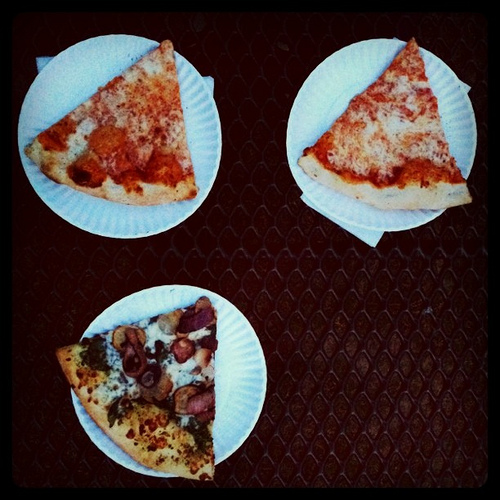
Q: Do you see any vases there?
A: No, there are no vases.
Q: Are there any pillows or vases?
A: No, there are no vases or pillows.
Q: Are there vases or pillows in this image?
A: No, there are no vases or pillows.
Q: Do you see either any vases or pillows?
A: No, there are no vases or pillows.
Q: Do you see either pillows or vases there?
A: No, there are no vases or pillows.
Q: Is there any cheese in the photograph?
A: Yes, there is cheese.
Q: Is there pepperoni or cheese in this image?
A: Yes, there is cheese.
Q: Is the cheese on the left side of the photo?
A: Yes, the cheese is on the left of the image.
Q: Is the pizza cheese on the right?
A: No, the cheese is on the left of the image.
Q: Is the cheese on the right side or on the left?
A: The cheese is on the left of the image.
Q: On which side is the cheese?
A: The cheese is on the left of the image.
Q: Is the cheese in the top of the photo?
A: Yes, the cheese is in the top of the image.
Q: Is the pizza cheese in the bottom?
A: No, the cheese is in the top of the image.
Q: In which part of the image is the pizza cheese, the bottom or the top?
A: The cheese is in the top of the image.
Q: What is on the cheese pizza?
A: The cheese is on the pizza.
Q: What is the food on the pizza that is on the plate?
A: The food is cheese.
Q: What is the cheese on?
A: The cheese is on the pizza.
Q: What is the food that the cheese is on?
A: The food is a pizza.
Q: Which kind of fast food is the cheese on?
A: The cheese is on the pizza.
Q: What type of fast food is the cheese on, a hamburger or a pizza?
A: The cheese is on a pizza.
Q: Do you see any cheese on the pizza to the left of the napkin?
A: Yes, there is cheese on the pizza.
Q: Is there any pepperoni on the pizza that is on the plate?
A: No, there is cheese on the pizza.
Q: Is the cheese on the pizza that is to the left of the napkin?
A: Yes, the cheese is on the pizza.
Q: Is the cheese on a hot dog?
A: No, the cheese is on the pizza.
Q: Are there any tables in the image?
A: Yes, there is a table.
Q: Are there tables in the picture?
A: Yes, there is a table.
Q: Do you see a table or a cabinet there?
A: Yes, there is a table.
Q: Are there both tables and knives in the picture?
A: No, there is a table but no knives.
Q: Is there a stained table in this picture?
A: Yes, there is a stained table.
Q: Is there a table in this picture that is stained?
A: Yes, there is a table that is stained.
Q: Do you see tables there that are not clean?
A: Yes, there is a stained table.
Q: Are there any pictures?
A: No, there are no pictures.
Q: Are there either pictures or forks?
A: No, there are no pictures or forks.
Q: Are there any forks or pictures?
A: No, there are no pictures or forks.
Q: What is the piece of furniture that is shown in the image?
A: The piece of furniture is a table.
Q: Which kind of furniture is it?
A: The piece of furniture is a table.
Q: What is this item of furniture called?
A: This is a table.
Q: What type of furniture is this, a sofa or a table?
A: This is a table.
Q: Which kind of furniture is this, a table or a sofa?
A: This is a table.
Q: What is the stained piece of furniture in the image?
A: The piece of furniture is a table.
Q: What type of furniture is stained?
A: The furniture is a table.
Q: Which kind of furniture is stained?
A: The furniture is a table.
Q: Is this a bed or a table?
A: This is a table.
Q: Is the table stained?
A: Yes, the table is stained.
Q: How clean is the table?
A: The table is stained.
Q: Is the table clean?
A: No, the table is stained.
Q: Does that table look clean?
A: No, the table is stained.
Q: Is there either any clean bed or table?
A: No, there is a table but it is stained.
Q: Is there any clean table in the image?
A: No, there is a table but it is stained.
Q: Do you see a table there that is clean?
A: No, there is a table but it is stained.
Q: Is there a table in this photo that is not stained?
A: No, there is a table but it is stained.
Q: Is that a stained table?
A: Yes, that is a stained table.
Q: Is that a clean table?
A: No, that is a stained table.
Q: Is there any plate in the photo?
A: Yes, there is a plate.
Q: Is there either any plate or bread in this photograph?
A: Yes, there is a plate.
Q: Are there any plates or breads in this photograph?
A: Yes, there is a plate.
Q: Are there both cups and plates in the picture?
A: No, there is a plate but no cups.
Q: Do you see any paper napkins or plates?
A: Yes, there is a paper plate.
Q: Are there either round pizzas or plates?
A: Yes, there is a round plate.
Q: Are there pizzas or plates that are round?
A: Yes, the plate is round.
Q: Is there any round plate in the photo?
A: Yes, there is a round plate.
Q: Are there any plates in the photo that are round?
A: Yes, there is a plate that is round.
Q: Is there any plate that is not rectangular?
A: Yes, there is a round plate.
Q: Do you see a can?
A: No, there are no cans.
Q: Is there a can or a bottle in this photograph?
A: No, there are no cans or bottles.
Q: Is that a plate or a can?
A: That is a plate.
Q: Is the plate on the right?
A: No, the plate is on the left of the image.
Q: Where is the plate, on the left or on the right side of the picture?
A: The plate is on the left of the image.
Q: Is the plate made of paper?
A: Yes, the plate is made of paper.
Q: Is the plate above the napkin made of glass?
A: No, the plate is made of paper.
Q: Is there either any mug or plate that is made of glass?
A: No, there is a plate but it is made of paper.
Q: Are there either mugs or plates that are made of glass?
A: No, there is a plate but it is made of paper.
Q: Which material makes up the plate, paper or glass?
A: The plate is made of paper.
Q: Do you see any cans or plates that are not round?
A: No, there is a plate but it is round.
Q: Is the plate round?
A: Yes, the plate is round.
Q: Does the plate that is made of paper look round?
A: Yes, the plate is round.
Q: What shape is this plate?
A: The plate is round.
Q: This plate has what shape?
A: The plate is round.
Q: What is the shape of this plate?
A: The plate is round.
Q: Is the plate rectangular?
A: No, the plate is round.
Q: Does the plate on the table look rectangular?
A: No, the plate is round.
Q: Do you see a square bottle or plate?
A: No, there is a plate but it is round.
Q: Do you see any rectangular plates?
A: No, there is a plate but it is round.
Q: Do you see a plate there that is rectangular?
A: No, there is a plate but it is round.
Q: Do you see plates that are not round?
A: No, there is a plate but it is round.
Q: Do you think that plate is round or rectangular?
A: The plate is round.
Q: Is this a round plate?
A: Yes, this is a round plate.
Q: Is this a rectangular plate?
A: No, this is a round plate.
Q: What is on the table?
A: The plate is on the table.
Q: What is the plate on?
A: The plate is on the table.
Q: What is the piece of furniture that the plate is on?
A: The piece of furniture is a table.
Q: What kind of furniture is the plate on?
A: The plate is on the table.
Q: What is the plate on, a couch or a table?
A: The plate is on a table.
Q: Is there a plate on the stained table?
A: Yes, there is a plate on the table.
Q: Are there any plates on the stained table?
A: Yes, there is a plate on the table.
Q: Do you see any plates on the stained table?
A: Yes, there is a plate on the table.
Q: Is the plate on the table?
A: Yes, the plate is on the table.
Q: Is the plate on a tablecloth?
A: No, the plate is on the table.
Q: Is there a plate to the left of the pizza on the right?
A: Yes, there is a plate to the left of the pizza.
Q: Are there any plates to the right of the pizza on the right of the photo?
A: No, the plate is to the left of the pizza.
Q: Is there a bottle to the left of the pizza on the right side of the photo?
A: No, there is a plate to the left of the pizza.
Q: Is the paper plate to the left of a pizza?
A: Yes, the plate is to the left of a pizza.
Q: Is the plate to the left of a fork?
A: No, the plate is to the left of a pizza.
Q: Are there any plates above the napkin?
A: Yes, there is a plate above the napkin.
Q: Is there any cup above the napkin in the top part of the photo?
A: No, there is a plate above the napkin.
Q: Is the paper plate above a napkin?
A: Yes, the plate is above a napkin.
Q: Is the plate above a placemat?
A: No, the plate is above a napkin.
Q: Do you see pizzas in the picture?
A: Yes, there is a pizza.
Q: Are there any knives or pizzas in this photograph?
A: Yes, there is a pizza.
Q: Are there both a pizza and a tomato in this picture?
A: No, there is a pizza but no tomatoes.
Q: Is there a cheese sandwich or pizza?
A: Yes, there is a cheese pizza.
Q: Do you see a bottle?
A: No, there are no bottles.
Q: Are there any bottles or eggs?
A: No, there are no bottles or eggs.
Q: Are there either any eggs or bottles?
A: No, there are no bottles or eggs.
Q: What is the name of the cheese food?
A: The food is a pizza.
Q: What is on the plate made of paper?
A: The pizza is on the plate.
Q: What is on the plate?
A: The pizza is on the plate.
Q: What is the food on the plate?
A: The food is a pizza.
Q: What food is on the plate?
A: The food is a pizza.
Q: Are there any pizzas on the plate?
A: Yes, there is a pizza on the plate.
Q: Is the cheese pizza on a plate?
A: Yes, the pizza is on a plate.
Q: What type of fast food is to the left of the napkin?
A: The food is a pizza.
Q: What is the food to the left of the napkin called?
A: The food is a pizza.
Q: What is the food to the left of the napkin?
A: The food is a pizza.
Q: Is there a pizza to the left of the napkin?
A: Yes, there is a pizza to the left of the napkin.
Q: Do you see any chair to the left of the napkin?
A: No, there is a pizza to the left of the napkin.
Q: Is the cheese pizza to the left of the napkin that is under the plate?
A: Yes, the pizza is to the left of the napkin.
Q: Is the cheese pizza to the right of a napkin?
A: No, the pizza is to the left of a napkin.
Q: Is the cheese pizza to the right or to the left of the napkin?
A: The pizza is to the left of the napkin.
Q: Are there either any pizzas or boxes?
A: Yes, there is a pizza.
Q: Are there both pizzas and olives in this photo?
A: No, there is a pizza but no olives.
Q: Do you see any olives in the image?
A: No, there are no olives.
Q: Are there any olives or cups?
A: No, there are no olives or cups.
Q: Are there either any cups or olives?
A: No, there are no olives or cups.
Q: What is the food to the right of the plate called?
A: The food is a pizza.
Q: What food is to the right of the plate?
A: The food is a pizza.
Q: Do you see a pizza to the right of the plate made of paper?
A: Yes, there is a pizza to the right of the plate.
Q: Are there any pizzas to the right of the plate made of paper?
A: Yes, there is a pizza to the right of the plate.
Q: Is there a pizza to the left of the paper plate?
A: No, the pizza is to the right of the plate.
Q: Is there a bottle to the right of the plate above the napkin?
A: No, there is a pizza to the right of the plate.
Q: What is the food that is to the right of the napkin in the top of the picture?
A: The food is a pizza.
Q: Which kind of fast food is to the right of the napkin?
A: The food is a pizza.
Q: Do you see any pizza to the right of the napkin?
A: Yes, there is a pizza to the right of the napkin.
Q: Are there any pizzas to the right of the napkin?
A: Yes, there is a pizza to the right of the napkin.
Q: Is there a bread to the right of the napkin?
A: No, there is a pizza to the right of the napkin.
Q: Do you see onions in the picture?
A: Yes, there is an onion.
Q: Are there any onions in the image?
A: Yes, there is an onion.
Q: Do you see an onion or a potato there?
A: Yes, there is an onion.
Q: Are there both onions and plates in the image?
A: Yes, there are both an onion and a plate.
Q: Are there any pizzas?
A: Yes, there is a pizza.